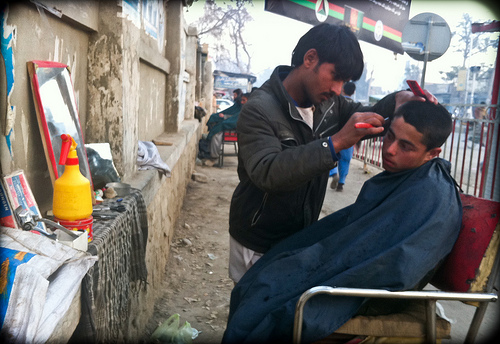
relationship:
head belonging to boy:
[381, 99, 454, 174] [231, 99, 468, 340]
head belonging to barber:
[288, 20, 363, 104] [207, 19, 436, 281]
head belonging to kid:
[230, 87, 242, 101] [203, 91, 249, 158]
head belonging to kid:
[235, 90, 247, 105] [206, 88, 240, 130]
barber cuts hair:
[207, 19, 436, 281] [399, 106, 450, 144]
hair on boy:
[399, 106, 450, 144] [221, 94, 458, 342]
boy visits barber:
[218, 90, 477, 340] [207, 19, 452, 280]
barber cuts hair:
[207, 19, 452, 280] [391, 100, 460, 145]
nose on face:
[330, 77, 345, 96] [309, 60, 351, 106]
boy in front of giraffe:
[231, 99, 468, 340] [393, 52, 482, 154]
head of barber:
[347, 100, 467, 188] [207, 19, 436, 281]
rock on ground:
[183, 237, 191, 248] [162, 149, 237, 336]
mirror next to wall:
[24, 59, 172, 223] [4, 3, 212, 332]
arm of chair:
[292, 285, 496, 342] [291, 188, 498, 341]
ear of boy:
[423, 142, 444, 159] [231, 99, 468, 340]